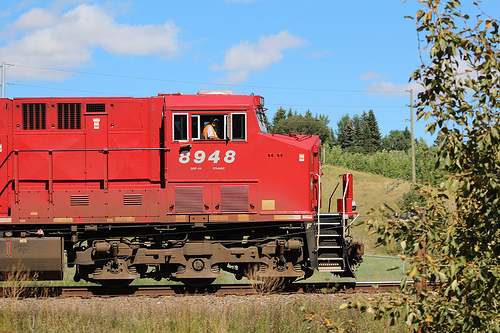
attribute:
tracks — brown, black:
[4, 266, 465, 300]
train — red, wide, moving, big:
[1, 85, 361, 297]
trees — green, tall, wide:
[268, 99, 422, 174]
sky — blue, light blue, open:
[1, 1, 493, 107]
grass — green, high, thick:
[12, 299, 484, 332]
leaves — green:
[273, 104, 411, 142]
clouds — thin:
[1, 4, 296, 88]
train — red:
[0, 73, 373, 273]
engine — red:
[0, 68, 374, 294]